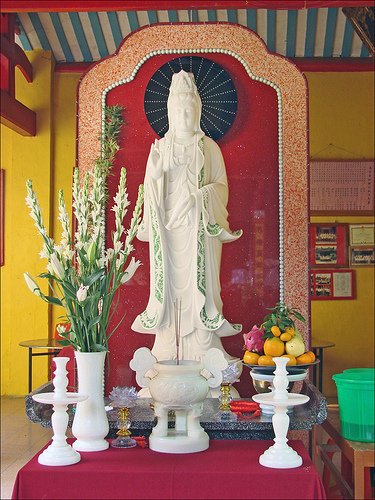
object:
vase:
[70, 348, 110, 454]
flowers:
[23, 269, 45, 306]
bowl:
[243, 359, 320, 373]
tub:
[330, 368, 375, 442]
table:
[309, 402, 375, 500]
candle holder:
[252, 353, 310, 467]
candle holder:
[32, 353, 88, 469]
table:
[17, 338, 69, 396]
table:
[310, 337, 335, 395]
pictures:
[346, 240, 375, 269]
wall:
[0, 52, 375, 400]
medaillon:
[143, 54, 238, 143]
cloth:
[14, 438, 327, 497]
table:
[10, 434, 323, 499]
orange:
[262, 336, 284, 357]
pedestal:
[249, 369, 312, 408]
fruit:
[296, 349, 316, 367]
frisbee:
[165, 200, 188, 231]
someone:
[129, 68, 243, 364]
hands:
[166, 192, 195, 232]